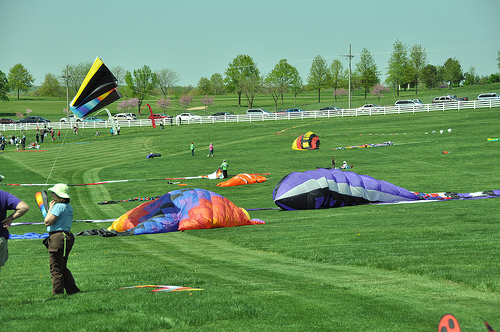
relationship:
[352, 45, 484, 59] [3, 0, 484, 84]
wires in sky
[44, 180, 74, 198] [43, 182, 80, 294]
hat of person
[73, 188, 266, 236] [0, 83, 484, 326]
balloon in grass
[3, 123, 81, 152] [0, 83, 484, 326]
people in grass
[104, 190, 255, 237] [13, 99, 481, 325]
balloon on ground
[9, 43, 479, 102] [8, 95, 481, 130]
trees behind fence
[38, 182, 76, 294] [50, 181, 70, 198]
person wearing hat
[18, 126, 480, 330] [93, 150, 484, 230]
field with kites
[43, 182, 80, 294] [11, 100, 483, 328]
person standing in field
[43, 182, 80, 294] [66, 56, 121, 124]
person flying kite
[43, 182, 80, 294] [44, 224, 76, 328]
person wearing dark brown pants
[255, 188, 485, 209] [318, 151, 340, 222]
blue silver and black deflated hot air balloon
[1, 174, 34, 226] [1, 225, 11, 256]
man in a blue shirt standing with h hand on h hip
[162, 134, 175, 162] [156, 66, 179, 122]
small cherry blossom tree in bloom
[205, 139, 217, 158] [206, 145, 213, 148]
woman in pink shirt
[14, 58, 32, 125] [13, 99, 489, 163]
tree in distance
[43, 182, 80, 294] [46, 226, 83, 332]
person white hat brown pants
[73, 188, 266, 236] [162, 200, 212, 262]
balloon multicolored kite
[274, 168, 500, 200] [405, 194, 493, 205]
blue and purple kite long tail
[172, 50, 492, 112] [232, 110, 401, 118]
row of cars along white fence.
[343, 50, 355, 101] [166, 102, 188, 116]
telephone pole along road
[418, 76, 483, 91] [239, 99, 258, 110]
house behind trees distance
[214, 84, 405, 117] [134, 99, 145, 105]
line of green trees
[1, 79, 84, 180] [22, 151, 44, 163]
group of people walking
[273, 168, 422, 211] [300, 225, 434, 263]
balloon on ground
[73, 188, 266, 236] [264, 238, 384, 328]
balloon on ground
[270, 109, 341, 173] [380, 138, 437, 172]
kite on ground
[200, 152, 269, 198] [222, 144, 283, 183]
kite on ground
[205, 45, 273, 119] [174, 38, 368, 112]
tree in distance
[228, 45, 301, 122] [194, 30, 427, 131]
tree in distance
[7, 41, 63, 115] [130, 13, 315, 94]
tree in distance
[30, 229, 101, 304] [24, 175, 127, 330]
pants on woman